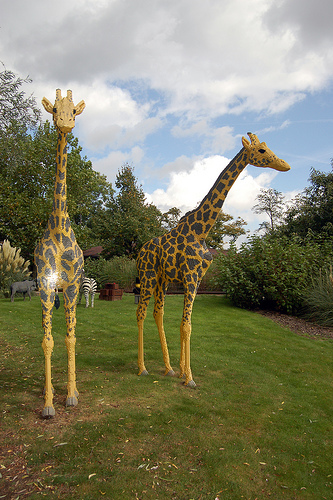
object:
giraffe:
[135, 129, 294, 391]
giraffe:
[31, 86, 86, 419]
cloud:
[0, 0, 333, 258]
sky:
[0, 2, 332, 259]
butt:
[91, 278, 98, 295]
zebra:
[78, 275, 98, 309]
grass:
[0, 291, 333, 500]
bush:
[0, 236, 32, 300]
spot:
[183, 243, 197, 259]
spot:
[165, 244, 176, 257]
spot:
[60, 229, 74, 250]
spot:
[58, 168, 68, 182]